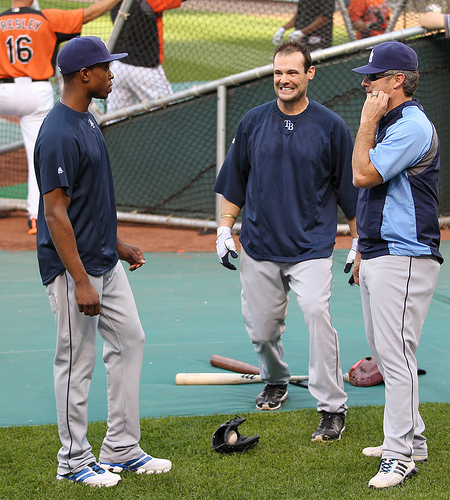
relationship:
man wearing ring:
[333, 38, 449, 305] [370, 90, 387, 102]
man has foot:
[188, 23, 351, 424] [239, 342, 300, 412]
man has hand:
[188, 23, 351, 424] [202, 202, 252, 271]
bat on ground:
[170, 360, 239, 403] [141, 331, 293, 427]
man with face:
[188, 23, 351, 424] [268, 38, 318, 103]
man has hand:
[188, 23, 351, 424] [181, 192, 246, 297]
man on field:
[188, 23, 351, 424] [224, 374, 391, 472]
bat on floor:
[170, 360, 239, 403] [155, 348, 260, 396]